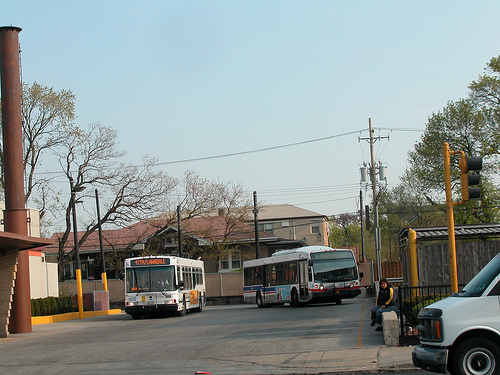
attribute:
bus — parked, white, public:
[121, 256, 207, 314]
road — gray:
[1, 296, 415, 375]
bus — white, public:
[242, 245, 361, 307]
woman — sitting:
[368, 274, 395, 332]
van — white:
[411, 253, 499, 374]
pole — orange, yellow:
[441, 141, 469, 297]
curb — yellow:
[31, 309, 121, 324]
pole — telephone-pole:
[357, 119, 392, 254]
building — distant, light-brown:
[46, 220, 302, 282]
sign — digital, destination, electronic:
[129, 257, 171, 266]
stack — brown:
[1, 25, 35, 335]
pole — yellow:
[76, 269, 85, 321]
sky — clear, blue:
[2, 2, 500, 241]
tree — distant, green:
[407, 101, 498, 227]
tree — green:
[469, 52, 500, 101]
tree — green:
[376, 185, 415, 260]